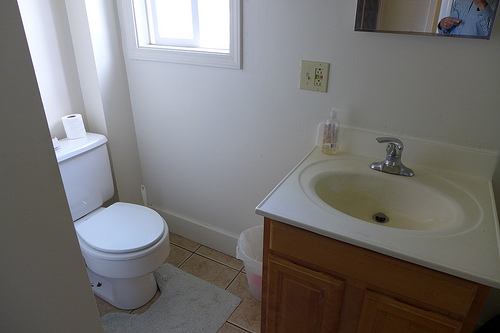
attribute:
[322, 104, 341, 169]
soap — liquid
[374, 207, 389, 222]
stopper — chrome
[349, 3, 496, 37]
mirror — silver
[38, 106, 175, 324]
toilet — clean, white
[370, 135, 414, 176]
faucet — metal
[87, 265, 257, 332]
mat — gray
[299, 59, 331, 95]
outlet — tan, wall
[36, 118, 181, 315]
toilet — white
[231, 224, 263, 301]
basket — white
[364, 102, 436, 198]
faucet — silver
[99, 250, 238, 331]
rug — white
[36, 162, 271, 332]
floor — beige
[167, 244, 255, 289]
tile — beige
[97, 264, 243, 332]
mat — small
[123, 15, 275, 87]
window — open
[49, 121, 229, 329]
toilet — white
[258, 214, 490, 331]
cabinet — brown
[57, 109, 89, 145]
roll — toilet paper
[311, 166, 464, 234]
sink — clean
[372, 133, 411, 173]
faucet — silver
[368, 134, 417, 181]
faucet — silver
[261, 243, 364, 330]
cabinets — wooden